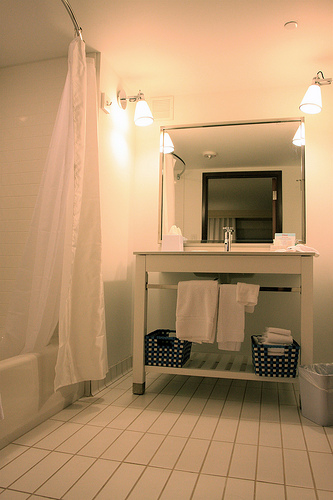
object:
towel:
[174, 279, 219, 343]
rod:
[145, 281, 302, 293]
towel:
[215, 282, 245, 351]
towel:
[235, 281, 260, 315]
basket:
[250, 334, 302, 379]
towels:
[260, 325, 293, 359]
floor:
[1, 452, 331, 500]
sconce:
[133, 98, 154, 130]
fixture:
[116, 88, 146, 112]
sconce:
[298, 83, 324, 117]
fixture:
[312, 70, 332, 88]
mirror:
[157, 118, 307, 248]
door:
[200, 170, 284, 242]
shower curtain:
[25, 38, 109, 392]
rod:
[58, 2, 83, 33]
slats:
[186, 353, 253, 378]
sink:
[131, 247, 319, 262]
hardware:
[222, 224, 236, 252]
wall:
[107, 134, 121, 255]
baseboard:
[90, 354, 131, 396]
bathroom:
[2, 0, 330, 499]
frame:
[157, 116, 307, 254]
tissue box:
[160, 232, 185, 254]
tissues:
[166, 222, 183, 236]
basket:
[143, 328, 191, 369]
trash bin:
[298, 362, 333, 427]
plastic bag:
[301, 362, 331, 391]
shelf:
[145, 352, 302, 385]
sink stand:
[131, 248, 317, 396]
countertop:
[131, 246, 320, 260]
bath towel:
[261, 335, 295, 346]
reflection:
[160, 131, 174, 154]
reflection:
[290, 121, 306, 149]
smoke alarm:
[283, 20, 297, 34]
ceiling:
[114, 2, 332, 87]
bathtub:
[1, 342, 81, 441]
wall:
[131, 83, 332, 367]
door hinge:
[272, 188, 276, 200]